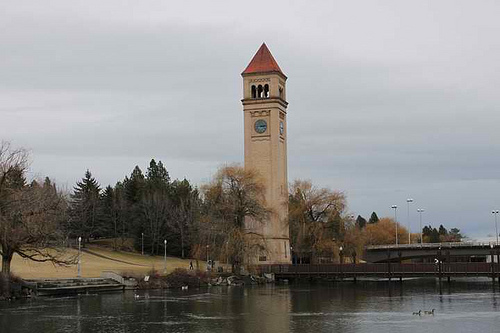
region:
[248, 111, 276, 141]
clock in tower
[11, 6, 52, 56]
white clouds in blue sky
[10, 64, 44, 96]
white clouds in blue sky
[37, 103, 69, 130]
white clouds in blue sky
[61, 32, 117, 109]
white clouds in blue sky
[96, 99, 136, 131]
white clouds in blue sky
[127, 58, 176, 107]
white clouds in blue sky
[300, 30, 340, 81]
white clouds in blue sky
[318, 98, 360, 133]
white clouds in blue sky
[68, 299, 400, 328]
The water is very calm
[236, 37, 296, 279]
A very tall building in the park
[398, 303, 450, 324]
The ducks are swimming in the water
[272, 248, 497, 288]
The walking bridge over the water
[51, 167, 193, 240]
The tree is tall with green leaves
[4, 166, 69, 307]
The tree is brown with a no leaves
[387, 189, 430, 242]
The street lights in the park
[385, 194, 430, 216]
The lamps on the poles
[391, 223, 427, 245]
The bottom of the lamps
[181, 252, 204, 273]
The man in the park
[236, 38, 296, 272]
tall tower near a lake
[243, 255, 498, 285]
wooden walkway extending over the lake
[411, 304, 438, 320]
two ducks on the lake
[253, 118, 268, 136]
clock facing the camera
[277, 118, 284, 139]
clock on right side of the tower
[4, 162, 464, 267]
line of trees on the shore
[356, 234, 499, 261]
bridge spanning the lake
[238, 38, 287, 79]
orange roof of the tower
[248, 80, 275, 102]
three windows on the tower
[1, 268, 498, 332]
water in the lake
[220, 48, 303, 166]
watch towe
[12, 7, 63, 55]
white clouds in blue sky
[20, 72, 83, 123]
white clouds in blue sky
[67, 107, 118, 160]
white clouds in blue sky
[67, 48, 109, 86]
white clouds in blue sky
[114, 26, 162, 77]
white clouds in blue sky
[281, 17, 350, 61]
white clouds in blue sky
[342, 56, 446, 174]
white clouds in blue sky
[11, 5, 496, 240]
beautiful calm sky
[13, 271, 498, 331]
sea water all around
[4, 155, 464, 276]
trees beside the water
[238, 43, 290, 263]
A tower by the water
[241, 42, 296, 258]
The tower is tan in color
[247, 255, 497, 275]
A bridge over the water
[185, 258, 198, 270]
A person walking around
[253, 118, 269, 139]
A clock on the tower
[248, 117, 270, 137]
The clock is white in color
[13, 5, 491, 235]
the sky is blue/white in color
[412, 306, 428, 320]
duck swimming in water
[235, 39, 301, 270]
tower at bottom of hill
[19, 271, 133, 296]
set of steps behind water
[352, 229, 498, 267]
bridge over calm water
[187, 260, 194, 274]
person walking on grass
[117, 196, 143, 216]
green leaves on the tree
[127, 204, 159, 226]
green leaves on the tree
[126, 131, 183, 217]
green leaves on the tree